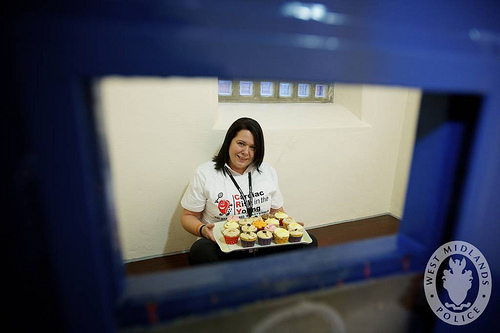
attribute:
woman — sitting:
[209, 110, 279, 212]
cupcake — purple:
[260, 232, 270, 239]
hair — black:
[258, 137, 267, 156]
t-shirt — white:
[197, 178, 216, 193]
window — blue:
[408, 91, 433, 212]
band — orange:
[200, 225, 204, 227]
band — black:
[197, 222, 200, 231]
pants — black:
[195, 245, 205, 257]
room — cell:
[120, 80, 396, 251]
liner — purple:
[260, 238, 269, 243]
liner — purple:
[294, 237, 300, 240]